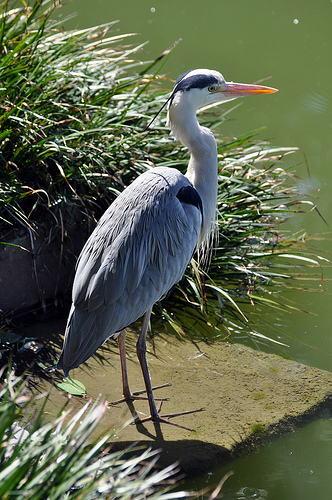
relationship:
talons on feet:
[109, 382, 204, 433] [107, 381, 205, 430]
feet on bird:
[107, 381, 205, 430] [55, 66, 278, 431]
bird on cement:
[55, 66, 278, 431] [34, 316, 331, 475]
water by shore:
[141, 403, 319, 497] [0, 329, 321, 485]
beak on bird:
[223, 82, 278, 97] [137, 63, 326, 346]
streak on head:
[169, 74, 215, 109] [168, 67, 229, 110]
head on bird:
[168, 67, 229, 110] [55, 66, 278, 431]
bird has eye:
[55, 66, 278, 431] [190, 71, 220, 99]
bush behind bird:
[0, 10, 318, 325] [58, 65, 270, 452]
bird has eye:
[55, 66, 278, 431] [206, 81, 219, 94]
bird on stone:
[55, 66, 278, 431] [177, 331, 305, 451]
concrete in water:
[34, 327, 322, 447] [229, 302, 314, 363]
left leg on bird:
[116, 331, 131, 399] [55, 66, 278, 431]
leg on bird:
[133, 318, 182, 439] [55, 64, 272, 361]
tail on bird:
[52, 310, 98, 379] [58, 55, 257, 444]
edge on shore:
[236, 416, 289, 446] [228, 290, 331, 496]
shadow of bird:
[120, 436, 240, 472] [29, 46, 309, 393]